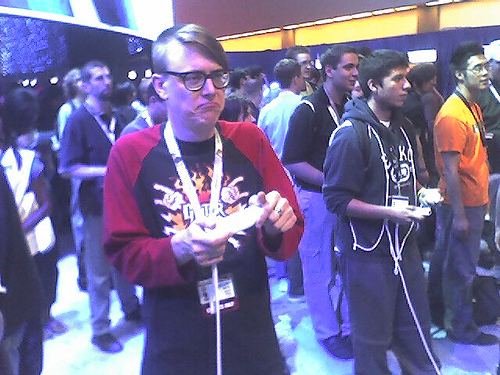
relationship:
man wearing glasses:
[98, 22, 307, 374] [163, 67, 231, 92]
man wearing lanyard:
[98, 22, 307, 374] [161, 122, 224, 215]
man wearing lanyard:
[58, 59, 146, 353] [79, 101, 116, 145]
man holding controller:
[98, 22, 307, 374] [204, 203, 264, 237]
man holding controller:
[320, 47, 445, 375] [409, 188, 441, 219]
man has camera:
[432, 43, 499, 347] [454, 87, 493, 147]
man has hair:
[432, 43, 499, 347] [447, 44, 484, 74]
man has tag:
[98, 22, 307, 374] [194, 271, 240, 319]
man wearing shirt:
[257, 58, 306, 158] [258, 90, 305, 158]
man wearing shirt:
[98, 22, 307, 374] [99, 116, 311, 375]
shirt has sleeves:
[99, 116, 311, 375] [77, 119, 305, 287]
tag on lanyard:
[194, 271, 240, 319] [161, 122, 224, 215]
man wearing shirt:
[432, 43, 499, 347] [431, 90, 491, 208]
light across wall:
[0, 1, 175, 37] [2, 0, 178, 87]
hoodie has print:
[320, 98, 421, 259] [380, 141, 414, 192]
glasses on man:
[163, 67, 231, 92] [98, 22, 307, 374]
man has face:
[98, 22, 307, 374] [172, 40, 229, 132]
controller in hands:
[204, 203, 264, 237] [189, 190, 298, 267]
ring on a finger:
[274, 207, 283, 215] [263, 197, 289, 231]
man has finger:
[98, 22, 307, 374] [263, 197, 289, 231]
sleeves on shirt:
[77, 119, 305, 287] [99, 116, 311, 375]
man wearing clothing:
[320, 47, 445, 375] [320, 100, 440, 374]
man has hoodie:
[320, 47, 445, 375] [320, 98, 421, 259]